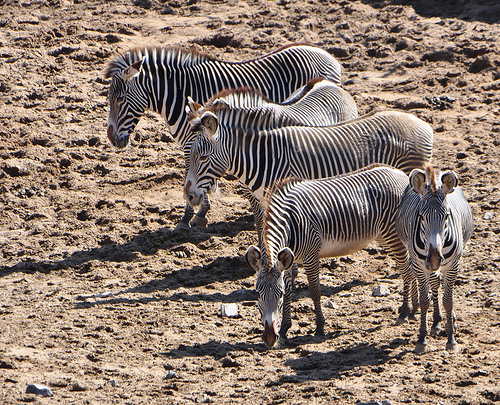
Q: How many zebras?
A: 5.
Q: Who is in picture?
A: Noone.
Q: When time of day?
A: Daytime.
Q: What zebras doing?
A: Standing still.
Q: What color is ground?
A: Brown.